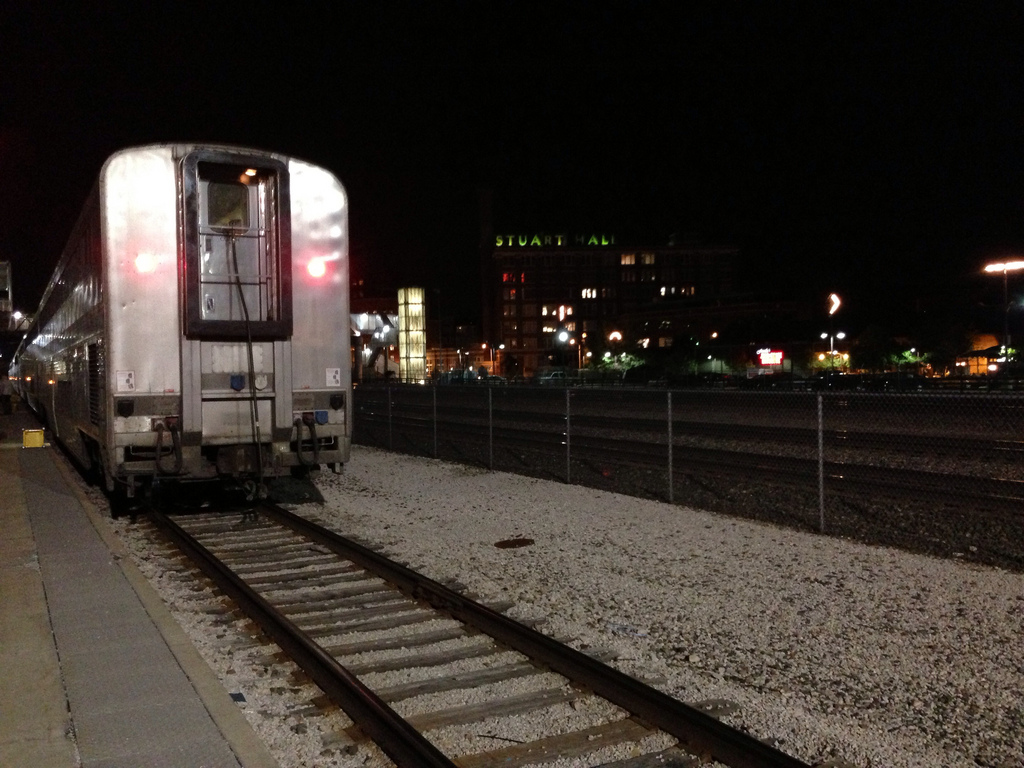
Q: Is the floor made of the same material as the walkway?
A: Yes, both the floor and the walkway are made of cement.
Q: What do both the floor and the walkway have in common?
A: The material, both the floor and the walkway are concrete.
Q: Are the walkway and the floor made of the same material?
A: Yes, both the walkway and the floor are made of concrete.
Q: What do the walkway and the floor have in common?
A: The material, both the walkway and the floor are concrete.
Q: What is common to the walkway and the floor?
A: The material, both the walkway and the floor are concrete.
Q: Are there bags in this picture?
A: No, there are no bags.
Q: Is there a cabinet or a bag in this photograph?
A: No, there are no bags or cabinets.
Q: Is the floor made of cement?
A: Yes, the floor is made of cement.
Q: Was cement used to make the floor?
A: Yes, the floor is made of cement.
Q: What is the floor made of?
A: The floor is made of concrete.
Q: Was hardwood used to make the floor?
A: No, the floor is made of concrete.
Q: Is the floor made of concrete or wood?
A: The floor is made of concrete.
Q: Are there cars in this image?
A: No, there are no cars.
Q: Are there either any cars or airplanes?
A: No, there are no cars or airplanes.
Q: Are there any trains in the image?
A: Yes, there is a train.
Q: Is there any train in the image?
A: Yes, there is a train.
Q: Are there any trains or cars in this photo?
A: Yes, there is a train.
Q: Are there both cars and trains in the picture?
A: No, there is a train but no cars.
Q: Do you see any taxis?
A: No, there are no taxis.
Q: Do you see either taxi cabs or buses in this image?
A: No, there are no taxi cabs or buses.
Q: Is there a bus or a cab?
A: No, there are no taxis or buses.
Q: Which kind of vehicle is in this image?
A: The vehicle is a train.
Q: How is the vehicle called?
A: The vehicle is a train.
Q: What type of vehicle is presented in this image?
A: The vehicle is a train.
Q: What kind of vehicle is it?
A: The vehicle is a train.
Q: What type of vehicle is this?
A: This is a train.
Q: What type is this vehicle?
A: This is a train.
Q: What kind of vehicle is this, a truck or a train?
A: This is a train.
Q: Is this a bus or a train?
A: This is a train.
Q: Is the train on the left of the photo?
A: Yes, the train is on the left of the image.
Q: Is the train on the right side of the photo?
A: No, the train is on the left of the image.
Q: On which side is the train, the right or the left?
A: The train is on the left of the image.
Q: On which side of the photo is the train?
A: The train is on the left of the image.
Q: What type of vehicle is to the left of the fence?
A: The vehicle is a train.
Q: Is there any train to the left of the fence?
A: Yes, there is a train to the left of the fence.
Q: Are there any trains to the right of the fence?
A: No, the train is to the left of the fence.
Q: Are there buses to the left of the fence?
A: No, there is a train to the left of the fence.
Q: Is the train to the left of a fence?
A: Yes, the train is to the left of a fence.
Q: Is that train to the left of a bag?
A: No, the train is to the left of a fence.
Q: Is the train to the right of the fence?
A: No, the train is to the left of the fence.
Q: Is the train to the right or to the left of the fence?
A: The train is to the left of the fence.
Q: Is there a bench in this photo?
A: No, there are no benches.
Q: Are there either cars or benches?
A: No, there are no benches or cars.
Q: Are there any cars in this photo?
A: No, there are no cars.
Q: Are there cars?
A: No, there are no cars.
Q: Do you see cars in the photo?
A: No, there are no cars.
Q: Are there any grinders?
A: No, there are no grinders.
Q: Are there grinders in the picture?
A: No, there are no grinders.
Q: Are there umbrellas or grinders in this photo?
A: No, there are no grinders or umbrellas.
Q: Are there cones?
A: No, there are no cones.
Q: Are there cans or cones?
A: No, there are no cones or cans.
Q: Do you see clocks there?
A: No, there are no clocks.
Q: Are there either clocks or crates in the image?
A: No, there are no clocks or crates.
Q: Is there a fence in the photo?
A: Yes, there is a fence.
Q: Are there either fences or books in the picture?
A: Yes, there is a fence.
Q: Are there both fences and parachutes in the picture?
A: No, there is a fence but no parachutes.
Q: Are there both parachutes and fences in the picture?
A: No, there is a fence but no parachutes.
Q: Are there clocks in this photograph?
A: No, there are no clocks.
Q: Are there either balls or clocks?
A: No, there are no clocks or balls.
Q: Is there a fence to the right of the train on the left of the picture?
A: Yes, there is a fence to the right of the train.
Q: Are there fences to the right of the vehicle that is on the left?
A: Yes, there is a fence to the right of the train.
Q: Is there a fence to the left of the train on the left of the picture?
A: No, the fence is to the right of the train.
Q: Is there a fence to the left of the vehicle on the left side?
A: No, the fence is to the right of the train.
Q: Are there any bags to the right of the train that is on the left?
A: No, there is a fence to the right of the train.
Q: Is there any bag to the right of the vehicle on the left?
A: No, there is a fence to the right of the train.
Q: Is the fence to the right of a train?
A: Yes, the fence is to the right of a train.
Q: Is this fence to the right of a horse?
A: No, the fence is to the right of a train.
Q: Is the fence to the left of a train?
A: No, the fence is to the right of a train.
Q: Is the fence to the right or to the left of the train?
A: The fence is to the right of the train.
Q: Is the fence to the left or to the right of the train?
A: The fence is to the right of the train.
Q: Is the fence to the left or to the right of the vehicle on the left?
A: The fence is to the right of the train.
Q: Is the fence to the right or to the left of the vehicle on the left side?
A: The fence is to the right of the train.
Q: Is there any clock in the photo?
A: No, there are no clocks.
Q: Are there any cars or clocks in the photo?
A: No, there are no clocks or cars.